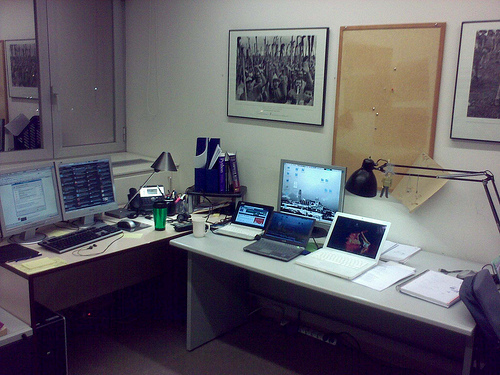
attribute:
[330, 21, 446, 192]
board — brown, empty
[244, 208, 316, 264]
laptop — black, white, gray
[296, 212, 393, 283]
laptop — white, open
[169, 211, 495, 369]
desk — white, gray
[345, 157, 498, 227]
lamp — black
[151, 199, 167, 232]
cup — black, green, drinking, tall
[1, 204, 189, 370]
desk — white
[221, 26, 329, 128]
art — black, white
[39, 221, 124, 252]
keyboard — black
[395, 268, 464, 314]
notepad — spiral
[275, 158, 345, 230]
computer monitor — gray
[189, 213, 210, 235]
mug — white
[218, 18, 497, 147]
images — framed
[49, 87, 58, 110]
lever — silver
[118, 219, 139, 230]
mouse — black, silver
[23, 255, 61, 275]
note papers — yellow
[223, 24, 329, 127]
picture frame — black, white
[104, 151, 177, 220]
lamp — gray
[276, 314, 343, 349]
cord — white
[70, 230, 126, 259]
ear phones — black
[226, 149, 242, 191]
book — purple